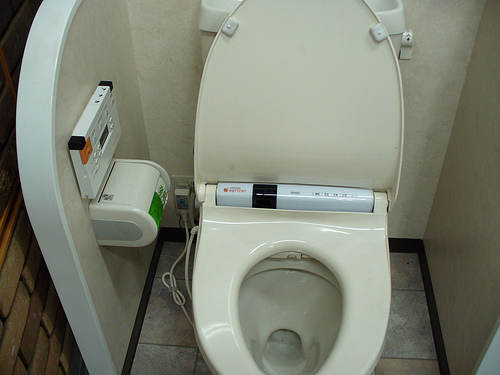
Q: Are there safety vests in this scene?
A: No, there are no safety vests.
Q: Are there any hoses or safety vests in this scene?
A: No, there are no safety vests or hoses.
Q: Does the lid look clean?
A: Yes, the lid is clean.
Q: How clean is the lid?
A: The lid is clean.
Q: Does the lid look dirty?
A: No, the lid is clean.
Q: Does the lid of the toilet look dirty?
A: No, the lid is clean.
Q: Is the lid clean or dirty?
A: The lid is clean.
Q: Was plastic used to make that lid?
A: Yes, the lid is made of plastic.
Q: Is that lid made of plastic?
A: Yes, the lid is made of plastic.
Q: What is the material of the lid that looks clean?
A: The lid is made of plastic.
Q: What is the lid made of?
A: The lid is made of plastic.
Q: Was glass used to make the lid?
A: No, the lid is made of plastic.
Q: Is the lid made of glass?
A: No, the lid is made of plastic.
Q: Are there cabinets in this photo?
A: No, there are no cabinets.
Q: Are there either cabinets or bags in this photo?
A: No, there are no cabinets or bags.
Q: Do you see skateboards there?
A: No, there are no skateboards.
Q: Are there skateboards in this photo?
A: No, there are no skateboards.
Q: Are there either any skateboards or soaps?
A: No, there are no skateboards or soaps.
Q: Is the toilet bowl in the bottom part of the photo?
A: Yes, the bowl is in the bottom of the image.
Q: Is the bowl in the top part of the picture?
A: No, the bowl is in the bottom of the image.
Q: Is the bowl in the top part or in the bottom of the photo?
A: The bowl is in the bottom of the image.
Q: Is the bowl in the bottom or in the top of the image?
A: The bowl is in the bottom of the image.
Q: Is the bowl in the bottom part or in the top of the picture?
A: The bowl is in the bottom of the image.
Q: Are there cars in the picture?
A: No, there are no cars.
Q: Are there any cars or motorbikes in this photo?
A: No, there are no cars or motorbikes.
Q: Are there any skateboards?
A: No, there are no skateboards.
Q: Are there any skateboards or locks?
A: No, there are no skateboards or locks.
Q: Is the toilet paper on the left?
A: Yes, the toilet paper is on the left of the image.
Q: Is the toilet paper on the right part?
A: No, the toilet paper is on the left of the image.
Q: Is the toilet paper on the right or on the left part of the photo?
A: The toilet paper is on the left of the image.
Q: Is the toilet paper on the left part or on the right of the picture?
A: The toilet paper is on the left of the image.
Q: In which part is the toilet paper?
A: The toilet paper is on the left of the image.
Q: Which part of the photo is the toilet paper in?
A: The toilet paper is on the left of the image.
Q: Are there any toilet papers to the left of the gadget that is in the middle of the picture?
A: Yes, there is a toilet paper to the left of the gadget.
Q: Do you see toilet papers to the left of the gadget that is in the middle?
A: Yes, there is a toilet paper to the left of the gadget.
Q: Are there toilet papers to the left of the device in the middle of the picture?
A: Yes, there is a toilet paper to the left of the gadget.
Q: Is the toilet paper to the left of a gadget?
A: Yes, the toilet paper is to the left of a gadget.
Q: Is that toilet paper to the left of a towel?
A: No, the toilet paper is to the left of a gadget.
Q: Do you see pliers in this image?
A: No, there are no pliers.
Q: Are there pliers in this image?
A: No, there are no pliers.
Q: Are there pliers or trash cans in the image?
A: No, there are no pliers or trash cans.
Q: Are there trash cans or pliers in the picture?
A: No, there are no pliers or trash cans.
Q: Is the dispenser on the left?
A: Yes, the dispenser is on the left of the image.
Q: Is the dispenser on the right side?
A: No, the dispenser is on the left of the image.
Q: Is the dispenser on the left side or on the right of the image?
A: The dispenser is on the left of the image.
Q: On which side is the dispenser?
A: The dispenser is on the left of the image.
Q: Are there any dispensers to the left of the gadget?
A: Yes, there is a dispenser to the left of the gadget.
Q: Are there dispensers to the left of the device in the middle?
A: Yes, there is a dispenser to the left of the gadget.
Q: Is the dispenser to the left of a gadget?
A: Yes, the dispenser is to the left of a gadget.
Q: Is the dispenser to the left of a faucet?
A: No, the dispenser is to the left of a gadget.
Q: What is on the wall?
A: The dispenser is on the wall.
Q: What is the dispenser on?
A: The dispenser is on the wall.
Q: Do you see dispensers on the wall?
A: Yes, there is a dispenser on the wall.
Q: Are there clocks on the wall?
A: No, there is a dispenser on the wall.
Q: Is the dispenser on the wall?
A: Yes, the dispenser is on the wall.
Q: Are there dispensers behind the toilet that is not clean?
A: Yes, there is a dispenser behind the toilet.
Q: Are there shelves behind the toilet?
A: No, there is a dispenser behind the toilet.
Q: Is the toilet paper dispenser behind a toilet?
A: Yes, the dispenser is behind a toilet.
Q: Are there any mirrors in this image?
A: No, there are no mirrors.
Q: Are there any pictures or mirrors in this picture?
A: No, there are no mirrors or pictures.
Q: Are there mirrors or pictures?
A: No, there are no mirrors or pictures.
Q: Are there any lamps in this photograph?
A: No, there are no lamps.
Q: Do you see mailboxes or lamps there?
A: No, there are no lamps or mailboxes.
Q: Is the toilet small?
A: Yes, the toilet is small.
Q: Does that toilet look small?
A: Yes, the toilet is small.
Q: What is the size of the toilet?
A: The toilet is small.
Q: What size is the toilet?
A: The toilet is small.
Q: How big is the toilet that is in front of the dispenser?
A: The toilet is small.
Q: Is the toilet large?
A: No, the toilet is small.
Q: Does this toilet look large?
A: No, the toilet is small.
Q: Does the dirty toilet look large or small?
A: The toilet is small.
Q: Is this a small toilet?
A: Yes, this is a small toilet.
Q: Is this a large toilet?
A: No, this is a small toilet.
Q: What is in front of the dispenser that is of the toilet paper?
A: The toilet is in front of the dispenser.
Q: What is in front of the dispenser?
A: The toilet is in front of the dispenser.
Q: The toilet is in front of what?
A: The toilet is in front of the dispenser.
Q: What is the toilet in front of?
A: The toilet is in front of the dispenser.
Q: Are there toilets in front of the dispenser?
A: Yes, there is a toilet in front of the dispenser.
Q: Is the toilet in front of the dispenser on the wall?
A: Yes, the toilet is in front of the dispenser.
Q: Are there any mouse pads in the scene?
A: No, there are no mouse pads.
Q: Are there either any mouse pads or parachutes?
A: No, there are no mouse pads or parachutes.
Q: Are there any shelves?
A: No, there are no shelves.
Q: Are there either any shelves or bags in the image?
A: No, there are no shelves or bags.